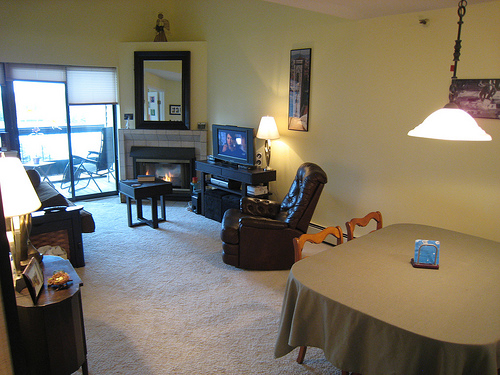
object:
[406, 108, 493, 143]
light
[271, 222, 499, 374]
table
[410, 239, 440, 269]
napkin holder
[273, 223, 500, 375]
cloth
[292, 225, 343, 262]
chairs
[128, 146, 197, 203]
fireplace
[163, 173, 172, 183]
flames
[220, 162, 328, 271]
recliner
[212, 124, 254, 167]
television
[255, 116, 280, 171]
lamp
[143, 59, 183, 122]
mirror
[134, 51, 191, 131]
frame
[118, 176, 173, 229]
table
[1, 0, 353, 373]
living room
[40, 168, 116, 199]
deck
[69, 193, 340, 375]
carpet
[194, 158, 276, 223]
table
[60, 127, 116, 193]
chairs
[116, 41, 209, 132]
wall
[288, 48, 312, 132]
picture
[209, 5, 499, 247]
wall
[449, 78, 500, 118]
picture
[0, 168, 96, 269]
sofa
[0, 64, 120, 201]
door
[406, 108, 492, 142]
shade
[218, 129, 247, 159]
screen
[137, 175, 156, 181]
book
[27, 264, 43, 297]
picture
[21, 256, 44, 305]
frame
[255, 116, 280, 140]
shade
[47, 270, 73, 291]
item